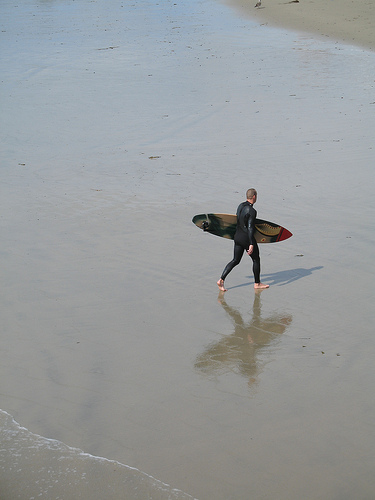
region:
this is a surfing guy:
[199, 185, 298, 303]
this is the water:
[170, 314, 266, 399]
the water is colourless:
[169, 411, 287, 456]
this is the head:
[246, 186, 260, 202]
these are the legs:
[209, 236, 284, 293]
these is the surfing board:
[198, 213, 233, 236]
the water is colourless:
[186, 103, 309, 175]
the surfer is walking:
[193, 187, 292, 298]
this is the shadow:
[196, 294, 302, 391]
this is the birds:
[250, 0, 265, 14]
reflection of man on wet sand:
[217, 284, 267, 398]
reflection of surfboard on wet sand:
[184, 314, 297, 375]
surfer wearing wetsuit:
[208, 179, 274, 297]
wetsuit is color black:
[218, 197, 267, 288]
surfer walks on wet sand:
[189, 172, 314, 316]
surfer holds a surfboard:
[185, 178, 297, 303]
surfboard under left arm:
[185, 180, 299, 309]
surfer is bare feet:
[212, 179, 280, 305]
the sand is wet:
[11, 11, 178, 498]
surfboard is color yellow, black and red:
[182, 207, 297, 250]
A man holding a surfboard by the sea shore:
[181, 174, 298, 297]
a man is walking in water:
[212, 164, 356, 356]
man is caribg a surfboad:
[205, 186, 304, 382]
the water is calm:
[116, 51, 231, 159]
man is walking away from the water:
[202, 194, 317, 348]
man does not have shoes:
[210, 271, 289, 321]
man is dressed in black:
[230, 184, 271, 300]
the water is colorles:
[47, 444, 132, 499]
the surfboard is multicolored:
[190, 197, 285, 245]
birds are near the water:
[252, 1, 278, 22]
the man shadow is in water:
[261, 249, 347, 306]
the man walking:
[217, 188, 267, 289]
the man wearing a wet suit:
[215, 187, 269, 290]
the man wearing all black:
[215, 188, 268, 290]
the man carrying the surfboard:
[216, 188, 269, 289]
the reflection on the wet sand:
[194, 289, 292, 385]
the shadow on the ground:
[222, 265, 322, 285]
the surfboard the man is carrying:
[191, 213, 292, 243]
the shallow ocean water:
[0, 409, 199, 498]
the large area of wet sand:
[0, 0, 373, 499]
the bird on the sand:
[254, 0, 261, 9]